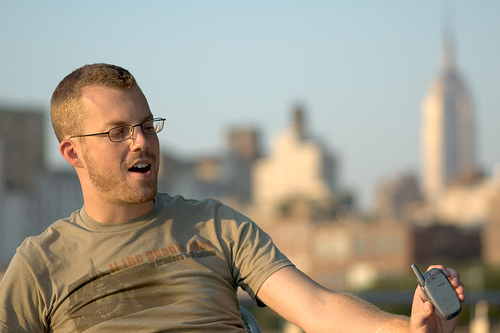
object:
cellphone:
[407, 262, 462, 321]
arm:
[213, 200, 412, 332]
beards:
[80, 147, 161, 203]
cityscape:
[0, 0, 499, 333]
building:
[419, 0, 484, 197]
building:
[249, 98, 344, 219]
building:
[190, 123, 261, 197]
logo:
[66, 232, 223, 332]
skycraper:
[421, 0, 477, 192]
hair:
[51, 62, 136, 141]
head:
[48, 63, 159, 204]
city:
[0, 1, 499, 333]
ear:
[58, 138, 83, 169]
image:
[66, 252, 176, 332]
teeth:
[138, 161, 148, 169]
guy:
[0, 63, 468, 332]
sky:
[0, 0, 499, 214]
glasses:
[68, 117, 167, 143]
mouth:
[125, 159, 153, 175]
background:
[2, 0, 499, 333]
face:
[78, 80, 160, 203]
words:
[105, 238, 217, 272]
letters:
[105, 240, 218, 272]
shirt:
[0, 194, 292, 332]